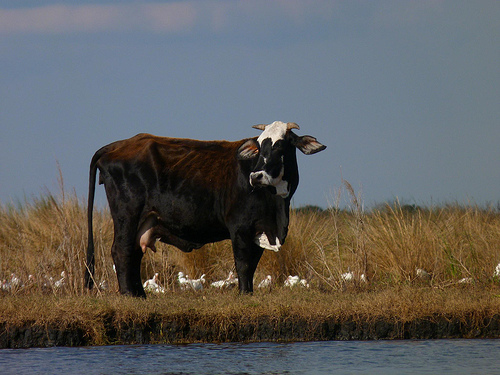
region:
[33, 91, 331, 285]
cow's body is brown and black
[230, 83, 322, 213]
cow's head is black and white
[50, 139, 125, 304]
cow's tail touches grass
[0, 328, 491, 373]
body of water in front of cow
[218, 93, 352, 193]
cow's head turned to right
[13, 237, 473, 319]
trash is in grass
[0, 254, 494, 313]
trash is white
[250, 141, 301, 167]
cow's eyes are black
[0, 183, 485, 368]
the grass is brown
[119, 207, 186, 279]
cow's utters are pink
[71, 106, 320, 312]
black and white cow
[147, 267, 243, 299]
small white birds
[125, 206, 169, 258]
cow udder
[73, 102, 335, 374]
cow standing next to water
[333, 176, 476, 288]
tall dry brown grass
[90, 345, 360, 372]
calm blue water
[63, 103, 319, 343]
cow standing on grass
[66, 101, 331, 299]
female cow with horns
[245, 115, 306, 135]
two horns on cow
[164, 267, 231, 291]
white birds standing in tall brown grass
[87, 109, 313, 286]
the cow is black and brown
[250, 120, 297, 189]
the cow has white spot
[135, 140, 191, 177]
the bones ca be seen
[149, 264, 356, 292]
there are birds on the ground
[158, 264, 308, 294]
the birds are white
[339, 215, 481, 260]
the grass is dry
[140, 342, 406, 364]
the water is blue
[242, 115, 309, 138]
the horns are small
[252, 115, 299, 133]
the horns are grey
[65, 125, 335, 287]
the cow is female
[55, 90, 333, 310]
a brown cow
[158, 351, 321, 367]
water below the cow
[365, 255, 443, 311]
brown grass near the cow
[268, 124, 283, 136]
white hair on the cows head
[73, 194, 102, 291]
cowa long tail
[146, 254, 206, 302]
birds below the cow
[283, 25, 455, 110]
grey skies above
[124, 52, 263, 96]
looks very cloudy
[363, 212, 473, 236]
grass looks very dead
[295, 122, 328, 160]
the cows ear is pink and brown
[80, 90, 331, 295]
a cow in the picture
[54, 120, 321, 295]
the cow is black and white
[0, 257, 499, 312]
white small birds on the grass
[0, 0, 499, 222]
the sky is very clear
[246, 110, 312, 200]
the head of a cow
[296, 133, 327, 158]
the ear of a cow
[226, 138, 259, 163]
the ear of a cow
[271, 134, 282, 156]
the eye of a cow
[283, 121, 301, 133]
the horn of a cow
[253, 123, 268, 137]
the horn of a cow